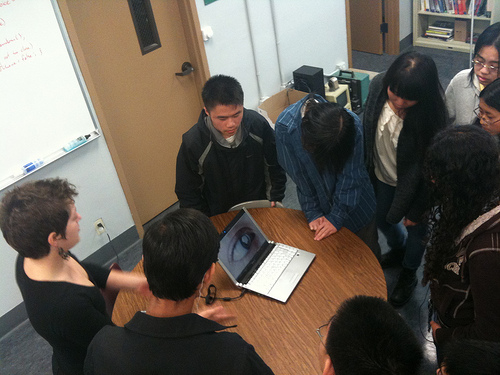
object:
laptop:
[216, 206, 316, 305]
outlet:
[92, 219, 108, 239]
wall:
[0, 2, 135, 321]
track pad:
[247, 243, 299, 294]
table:
[111, 206, 387, 374]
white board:
[0, 0, 96, 193]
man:
[173, 73, 287, 219]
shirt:
[275, 92, 379, 232]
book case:
[412, 0, 499, 54]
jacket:
[175, 105, 288, 217]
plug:
[97, 223, 103, 230]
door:
[55, 0, 211, 227]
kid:
[443, 21, 500, 127]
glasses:
[471, 58, 499, 73]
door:
[350, 1, 386, 68]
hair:
[383, 51, 448, 164]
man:
[82, 208, 276, 374]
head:
[142, 208, 221, 301]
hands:
[308, 214, 337, 241]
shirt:
[83, 311, 275, 375]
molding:
[242, 1, 288, 100]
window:
[128, 0, 163, 56]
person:
[0, 176, 236, 375]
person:
[421, 123, 500, 368]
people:
[2, 21, 500, 374]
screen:
[220, 213, 266, 280]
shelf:
[411, 1, 499, 51]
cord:
[200, 284, 248, 306]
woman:
[478, 78, 499, 136]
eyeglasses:
[472, 107, 498, 126]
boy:
[275, 91, 382, 258]